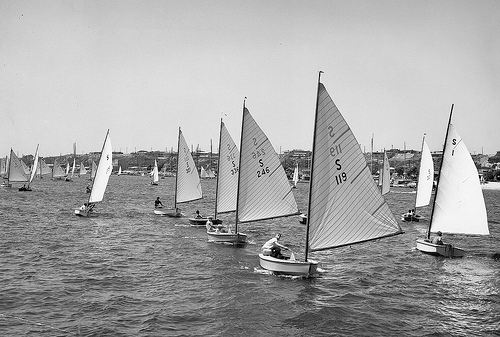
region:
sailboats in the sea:
[1, 77, 496, 282]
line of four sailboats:
[148, 68, 388, 304]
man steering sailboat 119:
[256, 225, 288, 257]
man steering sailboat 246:
[202, 212, 218, 229]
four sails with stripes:
[175, 93, 390, 243]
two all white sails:
[405, 128, 488, 235]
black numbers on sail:
[331, 171, 348, 186]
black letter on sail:
[331, 156, 345, 176]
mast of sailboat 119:
[300, 81, 315, 257]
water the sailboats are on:
[1, 173, 469, 335]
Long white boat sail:
[446, 155, 491, 239]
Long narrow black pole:
[436, 130, 443, 203]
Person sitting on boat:
[430, 218, 456, 252]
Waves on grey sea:
[19, 248, 228, 324]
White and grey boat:
[264, 254, 298, 275]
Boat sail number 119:
[331, 168, 353, 190]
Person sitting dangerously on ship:
[258, 229, 294, 254]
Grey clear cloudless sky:
[26, 15, 262, 89]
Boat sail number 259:
[251, 168, 275, 179]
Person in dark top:
[151, 194, 169, 205]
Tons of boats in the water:
[0, 141, 465, 271]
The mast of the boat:
[305, 76, 402, 253]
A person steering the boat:
[261, 235, 295, 255]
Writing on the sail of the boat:
[323, 126, 350, 186]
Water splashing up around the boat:
[250, 266, 300, 286]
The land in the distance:
[2, 142, 498, 187]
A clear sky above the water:
[1, 0, 498, 157]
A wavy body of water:
[0, 172, 498, 334]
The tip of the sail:
[315, 64, 324, 88]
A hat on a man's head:
[205, 212, 212, 218]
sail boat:
[281, 72, 395, 293]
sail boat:
[80, 123, 118, 228]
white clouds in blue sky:
[120, 33, 150, 53]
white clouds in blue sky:
[428, 39, 476, 79]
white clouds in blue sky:
[344, 48, 392, 70]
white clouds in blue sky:
[370, 23, 421, 80]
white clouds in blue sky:
[237, 21, 321, 72]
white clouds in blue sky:
[118, 18, 182, 52]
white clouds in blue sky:
[35, 18, 66, 36]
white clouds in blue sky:
[18, 26, 105, 108]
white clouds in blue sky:
[384, 52, 418, 93]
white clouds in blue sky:
[74, 59, 141, 87]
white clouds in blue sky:
[238, 75, 280, 97]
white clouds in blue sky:
[180, 18, 227, 42]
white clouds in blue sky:
[61, 19, 113, 57]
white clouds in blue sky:
[87, 21, 125, 58]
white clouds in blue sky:
[382, 56, 452, 113]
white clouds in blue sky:
[188, 33, 262, 80]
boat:
[151, 129, 213, 227]